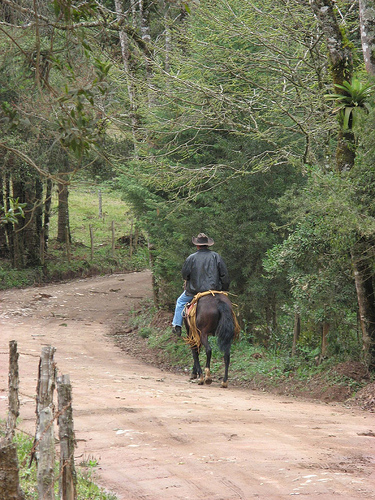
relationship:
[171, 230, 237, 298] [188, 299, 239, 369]
man riding horse